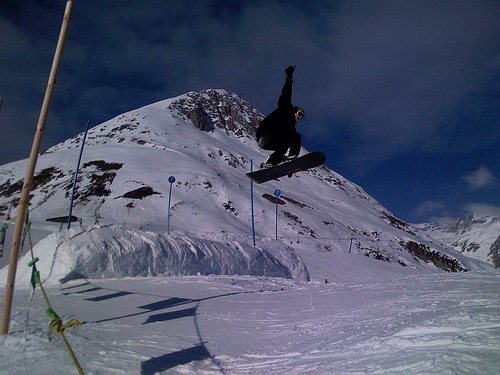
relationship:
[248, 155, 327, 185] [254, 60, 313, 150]
snowboard under man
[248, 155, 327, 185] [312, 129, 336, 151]
snowboard in air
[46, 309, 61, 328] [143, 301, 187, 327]
flag has shadow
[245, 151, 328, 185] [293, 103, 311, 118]
snowboard has sunglasses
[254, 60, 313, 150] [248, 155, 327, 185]
man on snowboard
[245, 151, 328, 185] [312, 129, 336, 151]
snowboard in air